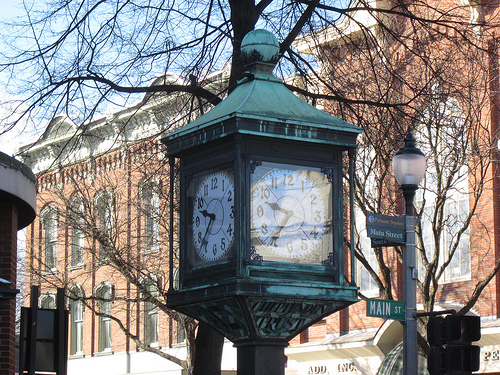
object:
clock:
[159, 27, 364, 374]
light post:
[389, 126, 430, 374]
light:
[390, 125, 427, 195]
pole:
[400, 191, 419, 374]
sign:
[366, 299, 405, 320]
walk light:
[425, 311, 482, 374]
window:
[65, 282, 84, 359]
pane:
[71, 298, 84, 324]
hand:
[201, 209, 217, 221]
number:
[210, 176, 220, 191]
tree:
[17, 0, 488, 113]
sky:
[1, 2, 234, 140]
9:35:
[249, 195, 297, 250]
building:
[20, 4, 496, 364]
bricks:
[481, 240, 495, 252]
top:
[394, 123, 426, 156]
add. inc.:
[304, 362, 354, 374]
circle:
[238, 26, 283, 69]